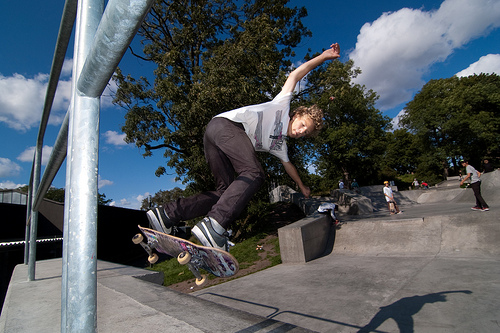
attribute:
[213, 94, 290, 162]
shirt — white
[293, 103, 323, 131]
blonde hair — flying, short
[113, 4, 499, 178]
trees — green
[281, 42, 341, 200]
arms — out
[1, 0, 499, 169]
sky — blue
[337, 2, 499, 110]
clouds — white, fluffy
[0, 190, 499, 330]
skatepark — cement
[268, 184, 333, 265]
cement wall — thick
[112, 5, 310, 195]
tree — large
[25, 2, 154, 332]
fence — metal